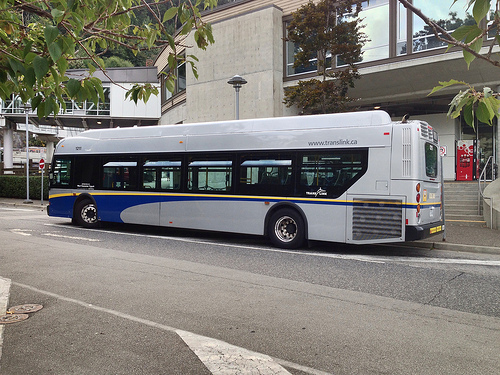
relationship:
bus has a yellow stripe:
[38, 106, 454, 260] [38, 192, 441, 208]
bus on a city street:
[38, 106, 454, 260] [2, 197, 499, 375]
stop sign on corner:
[34, 158, 47, 171] [0, 174, 47, 236]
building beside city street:
[157, 2, 500, 186] [2, 197, 499, 375]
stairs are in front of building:
[430, 175, 492, 230] [157, 2, 500, 186]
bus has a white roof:
[38, 106, 454, 260] [54, 106, 446, 154]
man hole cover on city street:
[2, 296, 45, 326] [2, 197, 499, 375]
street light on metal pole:
[226, 74, 250, 91] [228, 86, 246, 120]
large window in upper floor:
[277, 1, 494, 80] [137, 4, 500, 99]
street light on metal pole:
[17, 101, 36, 114] [23, 115, 33, 207]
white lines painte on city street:
[2, 273, 334, 373] [2, 197, 499, 375]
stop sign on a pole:
[34, 158, 47, 171] [37, 170, 49, 205]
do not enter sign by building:
[438, 141, 451, 158] [157, 2, 500, 186]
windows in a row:
[98, 155, 140, 190] [47, 148, 387, 201]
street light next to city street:
[226, 74, 250, 91] [2, 197, 499, 375]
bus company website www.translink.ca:
[38, 106, 454, 260] [305, 138, 363, 149]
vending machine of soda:
[450, 133, 483, 183] [457, 152, 473, 168]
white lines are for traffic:
[10, 222, 109, 253] [1, 124, 499, 254]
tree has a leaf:
[402, 3, 499, 131] [461, 28, 484, 69]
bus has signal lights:
[38, 106, 454, 260] [411, 179, 425, 219]